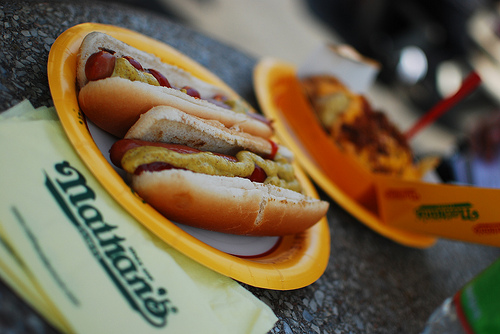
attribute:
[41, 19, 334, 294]
plate — yellow, white, white and yellow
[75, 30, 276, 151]
bun — hot dog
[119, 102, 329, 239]
bun — brown, white, hot dog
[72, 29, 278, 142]
bun — brown, white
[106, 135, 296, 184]
frank — red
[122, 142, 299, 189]
mustard — yellow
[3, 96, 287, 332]
napkins — paper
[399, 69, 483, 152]
utensil — red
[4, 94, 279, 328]
napkin — white, green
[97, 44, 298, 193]
condiments — ketchup, mustard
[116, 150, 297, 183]
mustard — spicy, brown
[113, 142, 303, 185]
mustard — brown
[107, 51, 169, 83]
mustard — brown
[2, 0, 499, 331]
counter top — gray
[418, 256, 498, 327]
bottle — clear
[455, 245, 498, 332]
label — red and green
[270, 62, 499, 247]
box — yellow, small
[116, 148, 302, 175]
mustard — squiggly, spicy, brown